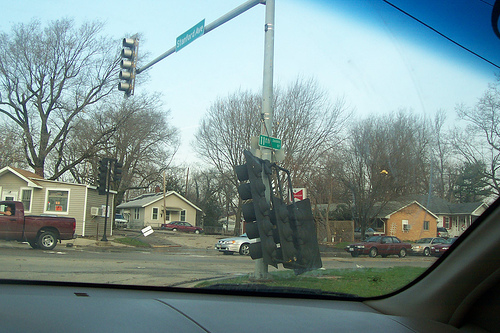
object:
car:
[343, 230, 415, 258]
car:
[212, 228, 280, 257]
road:
[0, 228, 439, 288]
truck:
[0, 196, 76, 253]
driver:
[0, 202, 15, 218]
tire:
[31, 229, 60, 250]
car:
[157, 220, 202, 236]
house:
[114, 189, 206, 233]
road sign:
[254, 134, 283, 152]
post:
[246, 0, 278, 281]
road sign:
[174, 17, 205, 53]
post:
[134, 0, 257, 74]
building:
[304, 200, 441, 247]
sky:
[0, 0, 499, 187]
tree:
[0, 15, 163, 187]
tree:
[51, 89, 183, 228]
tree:
[340, 107, 450, 202]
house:
[0, 163, 120, 240]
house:
[395, 193, 490, 241]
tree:
[332, 147, 412, 242]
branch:
[326, 165, 352, 183]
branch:
[304, 101, 332, 145]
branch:
[298, 133, 351, 178]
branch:
[291, 113, 319, 131]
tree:
[190, 73, 357, 236]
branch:
[203, 144, 224, 173]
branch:
[140, 131, 179, 154]